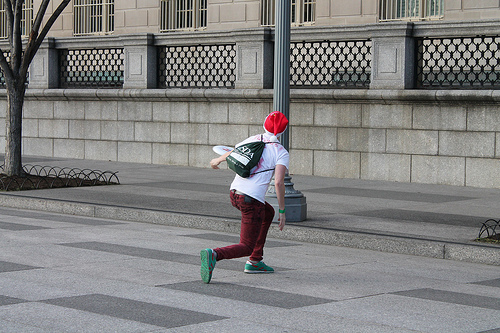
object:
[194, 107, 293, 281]
person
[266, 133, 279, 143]
ball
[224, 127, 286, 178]
bag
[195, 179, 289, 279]
pants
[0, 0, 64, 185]
tree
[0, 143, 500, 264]
sidewalk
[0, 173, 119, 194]
dirt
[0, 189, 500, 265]
curb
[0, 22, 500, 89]
concrete railing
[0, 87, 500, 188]
concrete wall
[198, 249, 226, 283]
sneakers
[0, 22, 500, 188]
patterned fencing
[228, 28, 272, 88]
stone columns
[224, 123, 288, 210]
t shirt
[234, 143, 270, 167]
lettering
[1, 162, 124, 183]
wire fencing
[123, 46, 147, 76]
detail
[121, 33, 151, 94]
stone column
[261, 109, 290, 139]
santa hat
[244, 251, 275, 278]
shoes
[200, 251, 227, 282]
shoe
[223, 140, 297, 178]
pack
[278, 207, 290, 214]
wristband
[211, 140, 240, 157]
frisbee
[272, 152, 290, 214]
arm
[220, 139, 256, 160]
arm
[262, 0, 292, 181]
lamp post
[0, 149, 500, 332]
ground